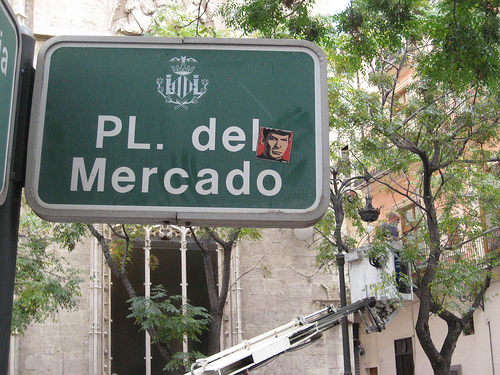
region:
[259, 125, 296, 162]
sticker of character Spock from Star Trek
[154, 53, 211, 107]
elaborate crest on street sign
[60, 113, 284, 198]
lettering reading Pl. del Mercado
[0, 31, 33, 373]
black pole holding up street signs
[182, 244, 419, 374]
cherry picker extended to upper level of a building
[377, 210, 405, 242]
workman in blue shirt in basket of cherry picker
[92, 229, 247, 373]
metal grate over open window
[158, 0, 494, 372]
leafy trees partially obscuring workman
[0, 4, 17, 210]
edge of green street sign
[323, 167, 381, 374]
ornate black pole holding street lamp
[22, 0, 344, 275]
a sign in a foreign language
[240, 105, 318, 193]
a random sticker on the sign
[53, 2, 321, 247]
a green sign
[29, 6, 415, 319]
signifies what street it is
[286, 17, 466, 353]
trees all around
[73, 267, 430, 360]
a metal object here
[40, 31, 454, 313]
a green sign with a sticker on it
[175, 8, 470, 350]
sunny day today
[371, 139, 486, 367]
tree with leaves and branches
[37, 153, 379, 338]
a building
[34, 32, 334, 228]
Green information sign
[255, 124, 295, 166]
Small image of Doctor Spock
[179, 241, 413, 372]
White metal construction boom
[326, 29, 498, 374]
Tall spindly tree with many branches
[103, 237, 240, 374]
Dark shadowed doorway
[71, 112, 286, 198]
Writing in Spanish on a street sign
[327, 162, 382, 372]
Outdoor lighting on a pole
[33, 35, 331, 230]
Green street sign with Spock sticker on it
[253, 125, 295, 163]
Colorful image of Spock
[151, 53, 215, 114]
A government emblem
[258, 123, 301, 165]
a red and black Dr. Spock sticker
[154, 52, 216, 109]
a white royal symbol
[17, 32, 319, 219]
a green and white street sign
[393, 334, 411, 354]
a circle above a door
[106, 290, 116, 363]
stone grommets on the frame of the doorway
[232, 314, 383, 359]
a white and black construction arm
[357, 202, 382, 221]
a black decorative iron bulb holder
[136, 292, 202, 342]
green busy leaves on a tree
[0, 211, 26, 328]
a pole supporting the street signs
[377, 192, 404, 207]
red brick on the building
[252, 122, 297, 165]
a sticker of Spock on a sign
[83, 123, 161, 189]
white letters on a green sign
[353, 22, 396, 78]
leaves in a tree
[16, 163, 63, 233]
a corner of a sign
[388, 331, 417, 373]
a window in a building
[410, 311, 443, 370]
a trunk of a tree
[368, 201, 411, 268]
a man in the bucket of a lift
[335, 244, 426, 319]
a bucket of a lift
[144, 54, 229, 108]
a white symbol on a sign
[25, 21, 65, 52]
bracket holding a sign on a pole